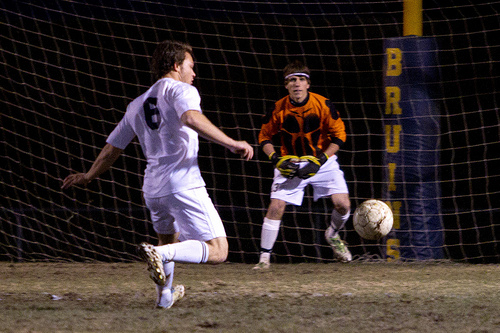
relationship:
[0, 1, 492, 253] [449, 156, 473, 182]
net has square hole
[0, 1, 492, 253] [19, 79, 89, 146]
net has square hole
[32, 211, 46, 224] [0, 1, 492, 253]
hole in net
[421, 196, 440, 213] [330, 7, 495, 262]
hole in net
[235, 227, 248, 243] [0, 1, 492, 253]
hole in net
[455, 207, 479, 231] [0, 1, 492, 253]
hole in a net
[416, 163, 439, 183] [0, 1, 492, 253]
hole in a net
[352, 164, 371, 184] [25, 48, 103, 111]
hole in a net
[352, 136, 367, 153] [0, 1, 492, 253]
hole in a net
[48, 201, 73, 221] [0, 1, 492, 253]
hole in a net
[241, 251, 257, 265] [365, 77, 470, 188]
hole in net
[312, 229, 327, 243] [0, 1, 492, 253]
hole in net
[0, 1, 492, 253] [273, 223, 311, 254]
net has hole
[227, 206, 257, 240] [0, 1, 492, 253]
hole in a net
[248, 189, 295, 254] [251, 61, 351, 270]
leg of a man